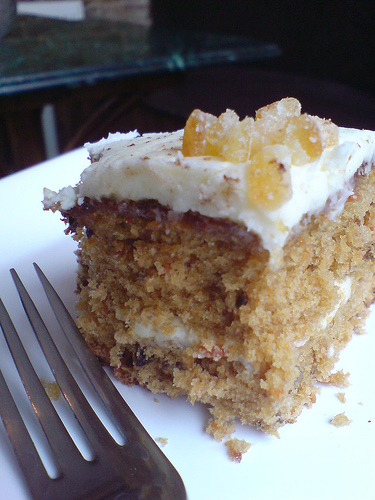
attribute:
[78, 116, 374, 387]
cake — carrot, brown, big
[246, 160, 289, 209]
topping — brown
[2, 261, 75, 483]
fork — silver, metallic, sharp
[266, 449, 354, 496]
plate — white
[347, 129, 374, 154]
cream — white, yellow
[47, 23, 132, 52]
table — black, white